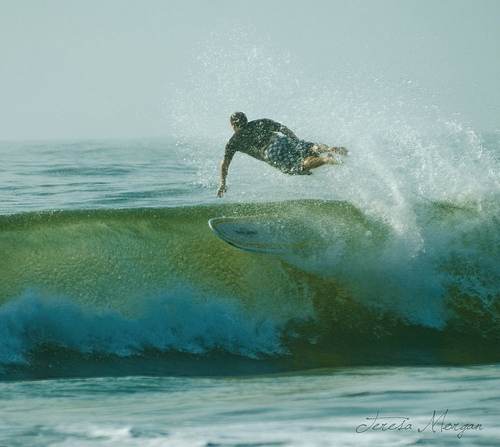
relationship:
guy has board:
[214, 110, 354, 199] [206, 211, 355, 254]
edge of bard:
[203, 217, 233, 251] [178, 210, 352, 301]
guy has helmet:
[214, 110, 354, 199] [228, 113, 258, 139]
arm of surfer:
[204, 151, 247, 209] [175, 67, 386, 238]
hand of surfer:
[214, 180, 239, 208] [175, 67, 386, 238]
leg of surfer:
[301, 120, 360, 183] [175, 67, 386, 238]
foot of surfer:
[324, 134, 357, 171] [175, 67, 386, 238]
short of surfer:
[268, 135, 320, 181] [175, 67, 386, 238]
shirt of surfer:
[238, 125, 284, 157] [175, 67, 386, 238]